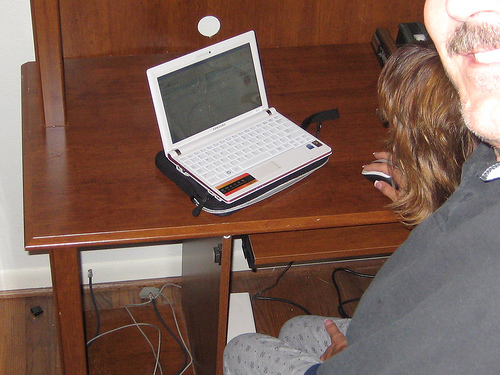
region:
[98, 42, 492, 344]
Two people at the desk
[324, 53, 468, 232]
The woman has brown hair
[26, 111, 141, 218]
The desk is made of wood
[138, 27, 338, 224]
The laptop on the table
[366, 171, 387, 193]
The fingernail of the woman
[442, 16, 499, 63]
The beard of the man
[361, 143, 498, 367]
The man has on a black shirt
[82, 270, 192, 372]
The cords of the floor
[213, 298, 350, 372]
The woman is wearing pajamas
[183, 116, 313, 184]
The keyboard on the laptop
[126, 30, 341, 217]
White laptop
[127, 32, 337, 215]
White laptop sitting on a laptop bag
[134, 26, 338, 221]
White laptop and bag on a desk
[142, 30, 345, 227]
White laptop on a computer desk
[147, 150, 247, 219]
Part of a laptop bag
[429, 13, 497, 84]
A man's smiling mouth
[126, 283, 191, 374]
Wires under a desk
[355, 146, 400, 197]
A woman's hand on a mouse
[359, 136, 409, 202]
A woman's hand with french manicure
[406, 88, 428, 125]
woman with brown hair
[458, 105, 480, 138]
grey hair on mans chin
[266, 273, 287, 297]
black wire on floor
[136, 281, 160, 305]
grey wire on floor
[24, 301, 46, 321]
black piece on floor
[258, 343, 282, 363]
woman wearing pajama pants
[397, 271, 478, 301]
man wearing grey sweater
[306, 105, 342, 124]
black strap on table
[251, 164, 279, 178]
white mouse pad on laptop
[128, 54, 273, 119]
screen of white laptop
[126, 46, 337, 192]
This is a laptop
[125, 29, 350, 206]
The laptop is sitting on a laptop case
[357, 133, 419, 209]
The woman's hand is on a mouse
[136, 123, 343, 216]
The laptop case is on the desk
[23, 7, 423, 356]
The desk is made of wood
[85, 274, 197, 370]
Cords laying on the ground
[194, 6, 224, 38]
Hole in the back of the desk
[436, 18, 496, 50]
Man with a mustache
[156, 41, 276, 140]
The computer is on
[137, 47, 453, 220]
The woman is looking at the computer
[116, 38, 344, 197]
A laptop on th desk.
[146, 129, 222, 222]
A black cover under the laptop.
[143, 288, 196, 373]
Cords on the floor.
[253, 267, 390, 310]
Black cords under the desk.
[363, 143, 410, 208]
A person with hand on the mouse.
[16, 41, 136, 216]
The desk is brown.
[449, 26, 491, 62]
The man has a moustache.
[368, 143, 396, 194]
Mouse on the table.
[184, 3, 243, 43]
A white cirle on the back of desk.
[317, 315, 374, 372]
Hands between the legs.